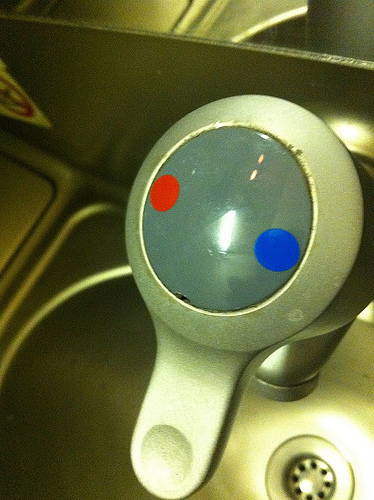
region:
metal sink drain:
[274, 435, 354, 499]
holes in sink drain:
[308, 458, 332, 476]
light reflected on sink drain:
[294, 470, 318, 497]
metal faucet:
[248, 322, 371, 410]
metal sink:
[0, 161, 373, 494]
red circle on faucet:
[143, 173, 188, 216]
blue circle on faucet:
[247, 219, 303, 278]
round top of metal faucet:
[117, 88, 351, 363]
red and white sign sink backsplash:
[1, 57, 59, 140]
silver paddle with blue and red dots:
[119, 90, 368, 496]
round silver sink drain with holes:
[262, 434, 358, 495]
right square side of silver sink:
[5, 164, 370, 489]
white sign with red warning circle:
[4, 58, 54, 129]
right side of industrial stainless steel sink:
[2, 0, 372, 492]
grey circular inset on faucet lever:
[135, 130, 321, 318]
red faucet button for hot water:
[145, 171, 189, 213]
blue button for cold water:
[247, 224, 302, 273]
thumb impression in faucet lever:
[128, 423, 204, 495]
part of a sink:
[332, 405, 342, 417]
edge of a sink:
[96, 432, 112, 448]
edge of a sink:
[180, 402, 189, 420]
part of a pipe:
[273, 384, 284, 412]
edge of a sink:
[185, 447, 192, 458]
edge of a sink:
[188, 413, 196, 432]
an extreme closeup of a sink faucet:
[114, 89, 368, 497]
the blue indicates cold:
[241, 212, 316, 270]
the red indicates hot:
[142, 153, 183, 218]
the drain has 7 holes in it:
[248, 418, 352, 499]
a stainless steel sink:
[72, 213, 131, 400]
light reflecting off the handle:
[133, 378, 224, 495]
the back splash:
[54, 70, 140, 118]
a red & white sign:
[1, 60, 57, 143]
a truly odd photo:
[13, 41, 368, 498]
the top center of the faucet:
[138, 119, 321, 315]